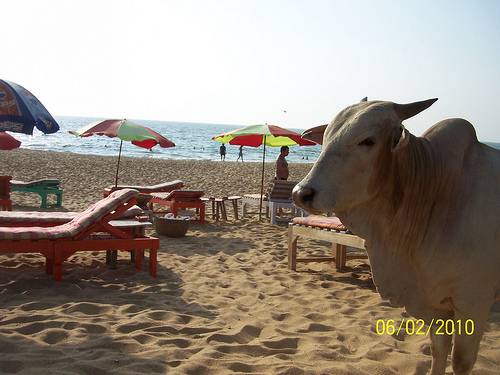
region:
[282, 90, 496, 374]
a cow on a beach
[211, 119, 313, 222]
a beach umbrella on a beach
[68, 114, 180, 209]
a beach umbrella on a beach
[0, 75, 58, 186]
a beach umbrella on a beach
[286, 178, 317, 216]
the nose of a cow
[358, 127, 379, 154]
the eye of a cow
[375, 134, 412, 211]
the ear of a cow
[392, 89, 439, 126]
a horn of a cow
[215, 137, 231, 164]
a person at the water's edge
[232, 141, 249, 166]
a person at the water's edge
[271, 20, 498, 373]
the animal is on the beach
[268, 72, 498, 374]
a large cow on the sand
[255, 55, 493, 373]
the cow is on the beach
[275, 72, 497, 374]
a cow with a white and brown hide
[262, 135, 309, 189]
he is not wearing a shirt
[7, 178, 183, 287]
a red wooden beach lounger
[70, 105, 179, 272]
this is an umbrella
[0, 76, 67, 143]
this umbrella is pepsi branded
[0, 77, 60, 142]
this is a Pepsi umbrella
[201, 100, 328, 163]
a red and neon green umbrella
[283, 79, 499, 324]
a cow on the beach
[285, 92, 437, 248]
the head of a tan cow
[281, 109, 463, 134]
the ears of a tan cow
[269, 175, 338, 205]
the nose of a tan cow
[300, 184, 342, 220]
the mouth of a tan cow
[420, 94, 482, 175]
the hump of a tan cow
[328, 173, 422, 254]
the neck of a tan cow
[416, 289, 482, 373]
the front legs of a tan cow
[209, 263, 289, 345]
the brown sand on a beach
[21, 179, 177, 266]
a bunch of red beach chairs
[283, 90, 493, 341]
white cow on sand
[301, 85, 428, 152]
cow has grey horns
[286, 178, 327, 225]
cow has brown nose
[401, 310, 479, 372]
cow has white legs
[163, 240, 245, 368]
sand is light brown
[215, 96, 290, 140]
red and yellow umbrella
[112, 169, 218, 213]
red chairs on sand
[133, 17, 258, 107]
white and blue sky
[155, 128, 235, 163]
water is light blue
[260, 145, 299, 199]
man standing under umbrella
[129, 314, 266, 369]
feet print in the sand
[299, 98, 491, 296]
light brown cow on the beach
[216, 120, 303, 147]
red and yellow umbrella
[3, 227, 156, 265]
wooden red lounge chair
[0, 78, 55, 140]
blue and white umbrella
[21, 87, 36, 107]
Pepsi logo on umbrella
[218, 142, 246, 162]
two people walking on the beach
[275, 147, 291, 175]
shirtless man standing on beach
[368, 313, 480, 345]
date when taken in yellow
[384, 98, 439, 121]
horn of a bull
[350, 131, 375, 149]
eye of a bull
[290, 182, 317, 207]
nose of a bull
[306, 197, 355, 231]
mouth of a bull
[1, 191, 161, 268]
red chair on a beach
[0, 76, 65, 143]
large wide beach umbrella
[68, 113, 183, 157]
large wide beach umbrella